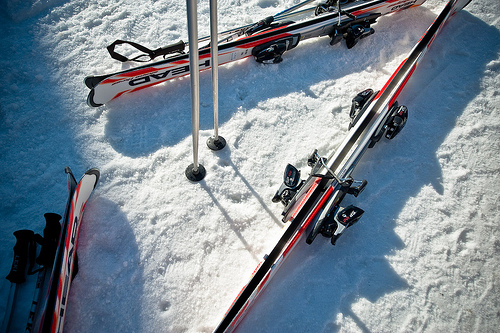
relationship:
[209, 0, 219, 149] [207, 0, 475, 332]
pole next to skating board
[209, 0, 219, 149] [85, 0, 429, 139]
pole next to skis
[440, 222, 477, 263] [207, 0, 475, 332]
footprint around skating board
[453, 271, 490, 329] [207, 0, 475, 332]
footprint around skating board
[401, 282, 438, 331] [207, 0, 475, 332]
footprint around skating board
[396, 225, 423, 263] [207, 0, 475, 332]
footprint around skating board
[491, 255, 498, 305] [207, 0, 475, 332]
footprint around skating board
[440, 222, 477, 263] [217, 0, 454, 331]
footprint around ski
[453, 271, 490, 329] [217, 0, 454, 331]
footprint around ski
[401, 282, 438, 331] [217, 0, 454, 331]
footprint around ski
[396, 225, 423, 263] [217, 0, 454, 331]
footprint around ski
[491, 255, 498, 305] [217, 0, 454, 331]
footprint around ski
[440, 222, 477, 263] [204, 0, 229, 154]
footprint around pole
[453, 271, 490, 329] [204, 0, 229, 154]
footprint around pole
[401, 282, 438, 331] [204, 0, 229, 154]
footprint around pole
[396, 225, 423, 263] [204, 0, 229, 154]
footprint around pole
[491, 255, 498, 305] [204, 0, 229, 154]
footprint around pole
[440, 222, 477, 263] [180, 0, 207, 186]
footprint around pole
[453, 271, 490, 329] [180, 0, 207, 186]
footprint around pole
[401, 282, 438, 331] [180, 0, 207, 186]
footprint around pole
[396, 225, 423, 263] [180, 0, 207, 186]
footprint around pole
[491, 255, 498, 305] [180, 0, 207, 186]
footprint around pole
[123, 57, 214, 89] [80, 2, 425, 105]
label on ski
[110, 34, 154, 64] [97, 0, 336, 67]
band for pole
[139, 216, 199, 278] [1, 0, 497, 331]
footprint in snow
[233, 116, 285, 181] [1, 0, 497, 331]
footprint in snow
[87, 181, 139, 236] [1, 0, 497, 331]
footprint in snow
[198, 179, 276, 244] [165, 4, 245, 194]
shadow of poles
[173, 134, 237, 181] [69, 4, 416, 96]
wheels of a skating board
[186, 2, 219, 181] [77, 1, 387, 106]
poles lie next to skis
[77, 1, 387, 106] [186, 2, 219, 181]
skis lie next to poles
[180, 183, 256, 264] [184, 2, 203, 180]
shadow by standing ski pole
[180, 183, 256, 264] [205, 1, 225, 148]
shadow by standing ski pole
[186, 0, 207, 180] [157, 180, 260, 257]
poles stuck in snow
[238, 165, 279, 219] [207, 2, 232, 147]
shadow of ski poles.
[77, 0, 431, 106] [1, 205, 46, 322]
skis laying next to poles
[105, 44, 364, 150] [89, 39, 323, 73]
shadow by skis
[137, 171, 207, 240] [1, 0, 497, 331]
sun on snow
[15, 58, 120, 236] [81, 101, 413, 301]
shadow on snow